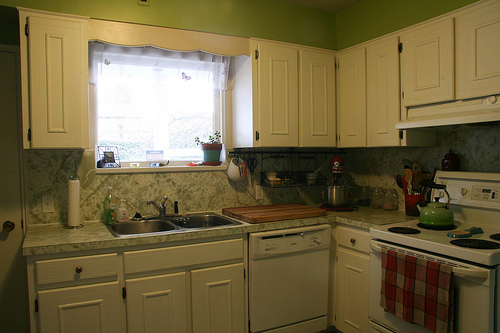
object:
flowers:
[216, 137, 220, 141]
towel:
[377, 248, 449, 332]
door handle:
[368, 239, 488, 279]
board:
[220, 203, 327, 225]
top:
[331, 207, 411, 233]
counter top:
[222, 204, 414, 233]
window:
[86, 43, 226, 167]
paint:
[203, 147, 221, 163]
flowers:
[193, 139, 201, 144]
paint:
[202, 143, 222, 149]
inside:
[113, 218, 172, 234]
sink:
[110, 217, 172, 237]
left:
[112, 214, 177, 234]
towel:
[66, 180, 84, 227]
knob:
[72, 264, 83, 274]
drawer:
[32, 250, 122, 286]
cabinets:
[230, 37, 300, 149]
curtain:
[90, 42, 232, 162]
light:
[93, 51, 220, 161]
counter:
[216, 201, 418, 233]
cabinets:
[21, 220, 127, 332]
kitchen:
[0, 0, 499, 332]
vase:
[200, 141, 223, 166]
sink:
[171, 211, 243, 229]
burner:
[414, 221, 458, 232]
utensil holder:
[403, 193, 429, 217]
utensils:
[400, 169, 412, 196]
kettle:
[413, 183, 454, 227]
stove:
[363, 170, 499, 331]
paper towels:
[66, 178, 81, 228]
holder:
[65, 174, 82, 231]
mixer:
[319, 155, 352, 208]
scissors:
[244, 158, 259, 188]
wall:
[23, 147, 335, 227]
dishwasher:
[247, 223, 330, 333]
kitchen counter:
[19, 208, 249, 256]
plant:
[193, 130, 225, 167]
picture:
[103, 152, 118, 165]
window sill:
[91, 161, 227, 174]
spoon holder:
[444, 226, 482, 239]